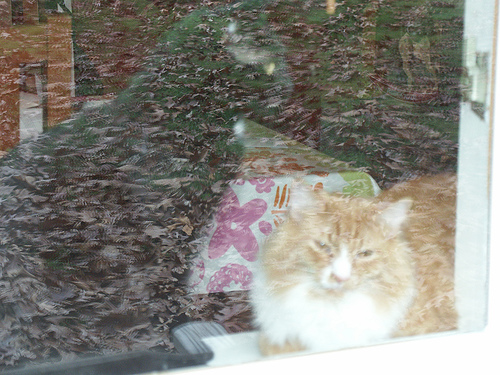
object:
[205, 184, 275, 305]
designs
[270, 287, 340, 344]
fur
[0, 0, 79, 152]
chair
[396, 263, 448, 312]
cat fur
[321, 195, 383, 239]
brown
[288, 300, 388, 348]
white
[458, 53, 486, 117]
latch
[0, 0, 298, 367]
cat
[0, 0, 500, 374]
window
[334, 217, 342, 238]
stripes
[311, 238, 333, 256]
eyes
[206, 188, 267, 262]
flower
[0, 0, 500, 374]
picture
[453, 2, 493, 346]
frame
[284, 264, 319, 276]
whiskers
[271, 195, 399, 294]
face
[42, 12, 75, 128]
bed post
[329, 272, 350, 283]
nose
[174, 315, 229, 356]
remote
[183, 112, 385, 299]
box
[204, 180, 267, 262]
floral details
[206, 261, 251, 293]
floral details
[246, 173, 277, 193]
floral details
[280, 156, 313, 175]
floral details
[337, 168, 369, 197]
floral details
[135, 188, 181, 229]
leafs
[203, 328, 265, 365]
table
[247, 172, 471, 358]
cat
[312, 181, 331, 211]
ear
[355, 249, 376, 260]
eyes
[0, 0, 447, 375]
reflection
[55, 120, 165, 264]
grass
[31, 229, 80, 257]
leaves